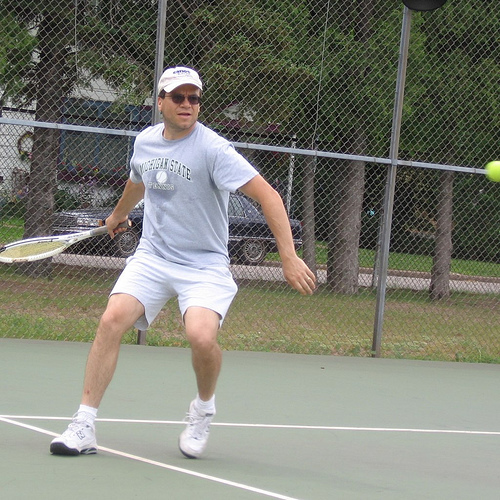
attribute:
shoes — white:
[44, 406, 106, 466]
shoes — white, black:
[174, 399, 219, 462]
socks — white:
[79, 407, 100, 421]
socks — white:
[194, 396, 219, 413]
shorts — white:
[102, 250, 245, 331]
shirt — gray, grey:
[122, 133, 256, 267]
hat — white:
[156, 64, 205, 98]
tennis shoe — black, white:
[48, 422, 99, 462]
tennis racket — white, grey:
[0, 225, 125, 269]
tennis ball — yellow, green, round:
[476, 161, 500, 180]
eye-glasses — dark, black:
[164, 91, 204, 108]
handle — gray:
[96, 226, 129, 238]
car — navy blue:
[42, 174, 310, 273]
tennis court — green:
[4, 1, 491, 493]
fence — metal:
[0, 5, 492, 358]